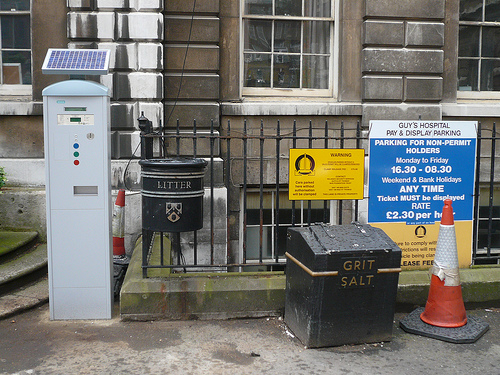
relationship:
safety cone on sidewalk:
[401, 197, 495, 346] [2, 304, 500, 374]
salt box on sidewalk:
[278, 217, 402, 352] [2, 304, 500, 374]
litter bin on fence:
[137, 153, 210, 235] [136, 114, 499, 279]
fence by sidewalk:
[136, 114, 499, 279] [2, 304, 500, 374]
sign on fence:
[289, 147, 364, 201] [136, 114, 499, 279]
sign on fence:
[366, 118, 479, 266] [136, 114, 499, 279]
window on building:
[240, 2, 338, 100] [0, 1, 499, 267]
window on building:
[457, 2, 500, 99] [0, 1, 499, 267]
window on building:
[240, 185, 335, 268] [0, 1, 499, 267]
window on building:
[474, 183, 499, 258] [0, 1, 499, 267]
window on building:
[1, 0, 35, 97] [0, 1, 499, 267]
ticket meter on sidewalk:
[38, 44, 117, 322] [2, 304, 500, 374]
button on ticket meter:
[72, 140, 81, 150] [38, 44, 117, 322]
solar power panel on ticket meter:
[40, 47, 111, 77] [38, 44, 117, 322]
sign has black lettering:
[289, 145, 366, 202] [318, 153, 358, 196]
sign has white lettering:
[366, 118, 479, 266] [374, 139, 457, 216]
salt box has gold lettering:
[278, 217, 402, 352] [340, 258, 376, 287]